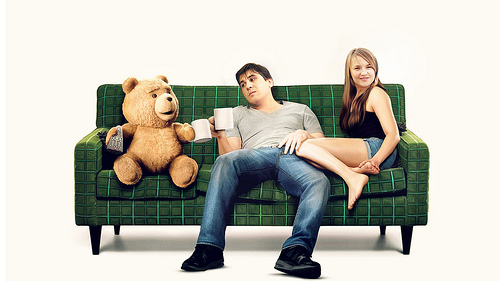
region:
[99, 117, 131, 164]
Remote control in teddy bears hand.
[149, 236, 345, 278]
A black pair of shoes.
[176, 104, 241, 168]
2 white coffee mugs.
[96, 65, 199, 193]
Teddy bear holding a remote.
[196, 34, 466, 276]
Two people sitting on a couch.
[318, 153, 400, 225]
A pair of bare feet.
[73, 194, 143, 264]
Wooden legs on furniture.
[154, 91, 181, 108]
Black nose of a teddy bear.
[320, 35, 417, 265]
A woman sitting down.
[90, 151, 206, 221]
Two feet of a teddy bear.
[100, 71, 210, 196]
a bear sitting on a couch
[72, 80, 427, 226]
the sofa is green with stripes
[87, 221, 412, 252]
the sofa has four black legs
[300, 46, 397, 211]
a girl is sitting on the couch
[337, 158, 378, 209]
the girl is barefoot sitting on the couch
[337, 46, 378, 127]
the girl has long brown hair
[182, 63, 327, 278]
a boy is lounging on the sofa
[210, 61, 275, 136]
the boy is holding a white cup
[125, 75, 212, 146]
the bear is holding a cup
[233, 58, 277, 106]
the boy on the sofa has brown hair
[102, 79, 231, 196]
Ted sitting on a couch holding a metronome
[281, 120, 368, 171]
A man with his hand on a woman's knee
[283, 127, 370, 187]
A woman with her knee on a man's leg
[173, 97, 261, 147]
A bear and a man clinking mugs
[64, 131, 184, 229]
A green couch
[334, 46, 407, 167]
A blond woman wearing a black sleeveless shirt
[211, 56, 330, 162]
A brown haired man wearing a gray t-shirt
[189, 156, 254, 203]
The pillow rises up from the man's weight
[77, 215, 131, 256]
Brown legs on the couch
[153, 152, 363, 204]
Three plaid pillows on a couch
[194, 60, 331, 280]
man sitting on couch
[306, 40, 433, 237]
girl sitting on couch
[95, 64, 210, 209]
teddy bear sitting on couch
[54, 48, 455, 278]
green plaid couch with four wooden legs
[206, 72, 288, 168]
man holding a coffee cup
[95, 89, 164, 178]
bear holding a tv remote control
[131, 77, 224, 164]
bear holding a coffee cup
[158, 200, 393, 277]
mans black shoes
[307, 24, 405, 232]
girl not wearing shoes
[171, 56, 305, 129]
man with dark hair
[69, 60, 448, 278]
the couch is green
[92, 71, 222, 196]
the bear is holding a mug and a remote control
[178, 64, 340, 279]
the man is holding a mug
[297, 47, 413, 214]
the girl is smiling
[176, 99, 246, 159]
the mugs are white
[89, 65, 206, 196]
the bear is brown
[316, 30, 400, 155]
the girl has long hair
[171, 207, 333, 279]
his shoes are black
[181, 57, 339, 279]
the man is wearing blue jeans and a gray shirt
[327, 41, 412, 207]
the girl is wearing a black shirt